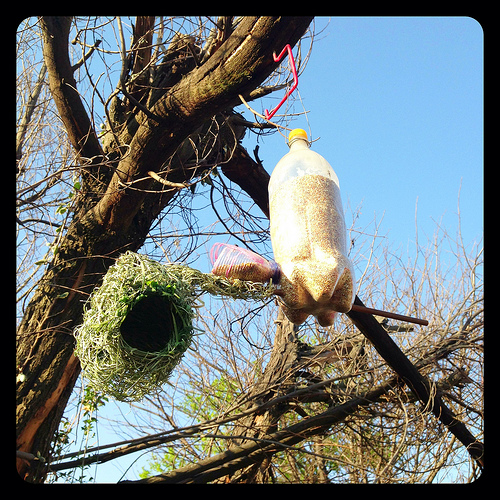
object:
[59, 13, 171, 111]
branches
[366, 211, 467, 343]
branches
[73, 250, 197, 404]
nest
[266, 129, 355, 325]
bottle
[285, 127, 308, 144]
cap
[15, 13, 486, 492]
tree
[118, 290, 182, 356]
hole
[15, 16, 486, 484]
sky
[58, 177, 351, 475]
leaves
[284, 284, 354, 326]
bottom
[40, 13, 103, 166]
branch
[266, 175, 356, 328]
seed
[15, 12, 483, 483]
vines